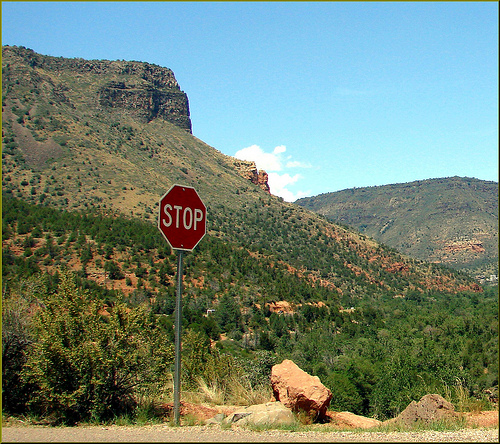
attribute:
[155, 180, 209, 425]
stop sign — red, eight-sided, nowhere, angled left, white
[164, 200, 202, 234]
stop letters — white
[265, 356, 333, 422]
rock — big, brown, leaning, red, upright, large, protruding, porous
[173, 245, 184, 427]
pole — grey, silvertone metal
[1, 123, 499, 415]
trees — many, green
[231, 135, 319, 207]
clouds — white, puffy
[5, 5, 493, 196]
sky — blue, clear blue, beautiful, crystal clear, clear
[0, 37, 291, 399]
mountain — big, rocky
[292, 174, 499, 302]
mountain — big, barren, distant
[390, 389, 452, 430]
rock — brown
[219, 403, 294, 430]
rock — yellow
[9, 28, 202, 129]
mountaintop — squarish, angular, sharp, cut off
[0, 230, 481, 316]
earth — rusty red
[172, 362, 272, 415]
weeds — greenish yellow, dead, dry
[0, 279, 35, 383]
bush — dead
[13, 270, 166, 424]
bushes — lush green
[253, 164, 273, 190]
boulder — alone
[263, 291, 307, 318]
patch — bare dirt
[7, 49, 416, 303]
vegetation — green